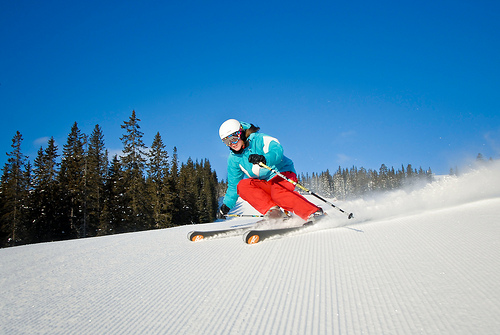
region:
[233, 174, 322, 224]
red pants on a skier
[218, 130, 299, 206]
a blue and white coat on a skier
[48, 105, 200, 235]
a group of pine trees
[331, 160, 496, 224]
snow kicked up behind a skier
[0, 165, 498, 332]
a white snowy slope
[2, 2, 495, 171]
a bright blue sky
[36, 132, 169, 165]
clouds behind the trees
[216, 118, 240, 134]
a white helmet on a skier's head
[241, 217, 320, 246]
a black ski with an orange circle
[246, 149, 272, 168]
a black glove on a hand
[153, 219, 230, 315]
the snow is white and clear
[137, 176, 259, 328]
the snow is white and clear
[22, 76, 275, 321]
the snow is white and clear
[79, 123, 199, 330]
the snow is white and clear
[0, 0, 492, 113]
cloudless sky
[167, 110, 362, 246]
girl skiing down a mountain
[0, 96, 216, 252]
pine trees on a ski slope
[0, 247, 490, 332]
perfectly raked snow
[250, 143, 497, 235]
snow being blown up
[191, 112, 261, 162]
ski safety gear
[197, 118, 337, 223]
girl wearng blue jacket and red pants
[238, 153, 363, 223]
ski pole in girl's hand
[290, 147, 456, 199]
trees with snow in them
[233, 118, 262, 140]
blue hair tie in girl's hair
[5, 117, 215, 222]
tall evergreen trees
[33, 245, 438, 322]
smooth prepared snow surface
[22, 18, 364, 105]
deep bright blue sky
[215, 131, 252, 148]
colorful snow googles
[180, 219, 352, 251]
black skies with orange circle pattern underneath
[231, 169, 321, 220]
red-orange ski pants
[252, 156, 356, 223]
black and white ski pole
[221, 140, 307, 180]
aqua blue and white ski jacket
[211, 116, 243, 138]
white ski helmet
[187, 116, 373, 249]
young woman skiing down hill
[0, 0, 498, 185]
clear bright blue sky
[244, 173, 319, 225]
red snow pants on skiier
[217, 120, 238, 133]
white helmet on skiier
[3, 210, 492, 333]
smooth snow on hill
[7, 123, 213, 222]
row of evergreen trees in background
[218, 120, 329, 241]
skiier skiing down the hill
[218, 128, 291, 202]
woman skiing downhill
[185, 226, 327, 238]
two black skiis with orange design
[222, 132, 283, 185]
aqua blue snow jacket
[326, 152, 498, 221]
trail of snow behind woman